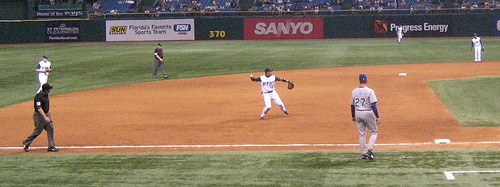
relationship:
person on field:
[19, 82, 62, 152] [95, 44, 248, 180]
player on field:
[244, 69, 304, 119] [95, 44, 248, 180]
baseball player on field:
[343, 73, 382, 158] [95, 44, 248, 180]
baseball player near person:
[343, 73, 382, 158] [19, 82, 62, 152]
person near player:
[19, 82, 62, 152] [244, 69, 304, 119]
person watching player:
[19, 82, 62, 152] [244, 69, 304, 119]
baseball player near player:
[343, 73, 382, 158] [244, 69, 304, 119]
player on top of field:
[244, 69, 304, 119] [95, 44, 248, 180]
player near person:
[244, 69, 304, 119] [19, 82, 62, 152]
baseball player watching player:
[343, 73, 382, 158] [244, 69, 304, 119]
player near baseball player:
[244, 69, 304, 119] [343, 73, 382, 158]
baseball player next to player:
[343, 73, 382, 158] [244, 69, 304, 119]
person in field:
[19, 82, 62, 152] [95, 44, 248, 180]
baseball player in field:
[343, 73, 382, 158] [95, 44, 248, 180]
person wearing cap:
[19, 76, 67, 147] [38, 81, 54, 95]